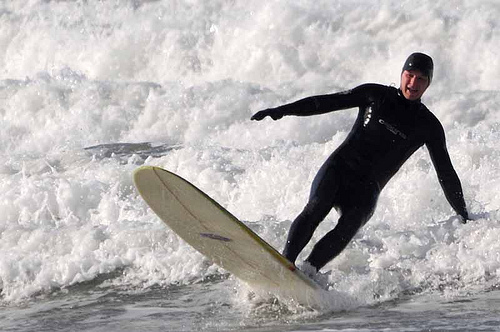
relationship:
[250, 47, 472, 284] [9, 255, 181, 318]
man in water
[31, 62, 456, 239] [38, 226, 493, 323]
foam in ocean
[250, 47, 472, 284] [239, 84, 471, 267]
man wearing body suit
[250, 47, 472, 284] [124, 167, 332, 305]
man riding surfboard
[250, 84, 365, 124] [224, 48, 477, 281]
arm on person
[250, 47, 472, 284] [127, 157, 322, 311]
man standing on surfboard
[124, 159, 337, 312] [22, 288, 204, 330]
surfboard in water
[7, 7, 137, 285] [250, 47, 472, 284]
wave behind man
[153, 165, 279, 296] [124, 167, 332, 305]
line down center of surfboard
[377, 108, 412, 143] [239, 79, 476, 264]
logo on body suit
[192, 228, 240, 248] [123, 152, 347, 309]
logo on bottom of surfboard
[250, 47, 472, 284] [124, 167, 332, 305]
man on surfboard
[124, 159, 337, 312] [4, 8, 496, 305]
surfboard in ocean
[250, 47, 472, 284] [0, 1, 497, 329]
man in ocean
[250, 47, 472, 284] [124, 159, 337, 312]
man on surfboard